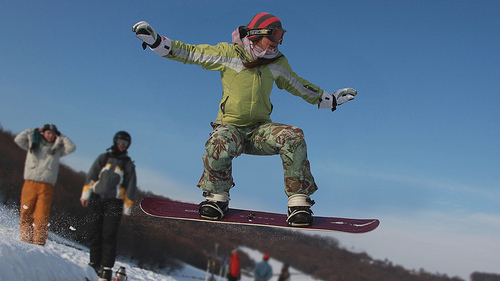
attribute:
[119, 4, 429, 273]
snowboarder — in the air 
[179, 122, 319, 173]
knees — bent 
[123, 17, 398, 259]
snowboarder — doing a trick 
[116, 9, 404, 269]
person — snowboarding 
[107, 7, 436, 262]
person — doing a trick , doing a stunt 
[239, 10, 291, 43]
helmet — red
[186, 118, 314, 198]
pants — camouflage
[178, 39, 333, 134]
jacket — green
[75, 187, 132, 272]
pants — black 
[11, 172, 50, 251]
pants — brown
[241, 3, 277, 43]
marvin — red, black 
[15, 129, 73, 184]
jacket — grey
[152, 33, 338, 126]
snowboarding jacket — lime green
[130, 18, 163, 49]
glove — white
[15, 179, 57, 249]
snowboarding pants — burnt orange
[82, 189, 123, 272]
snowboarding pants — black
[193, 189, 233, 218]
snowboarding boots — black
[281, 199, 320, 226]
snowboarding boots — black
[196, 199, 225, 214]
bindings — black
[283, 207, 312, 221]
bindings — black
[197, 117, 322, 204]
snowboarding pants — green, brown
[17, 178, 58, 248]
pants — tan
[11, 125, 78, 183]
jacket — grey, winter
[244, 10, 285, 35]
beanie — black, red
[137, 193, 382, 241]
snowboard — deep purple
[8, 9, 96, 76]
sky — blue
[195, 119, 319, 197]
pants — camouflage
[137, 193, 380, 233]
snowboard — burgundy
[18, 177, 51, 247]
pants — orange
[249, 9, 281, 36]
hat — pink, gray, striped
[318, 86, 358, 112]
left glove — white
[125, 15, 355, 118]
hands — grey gloved